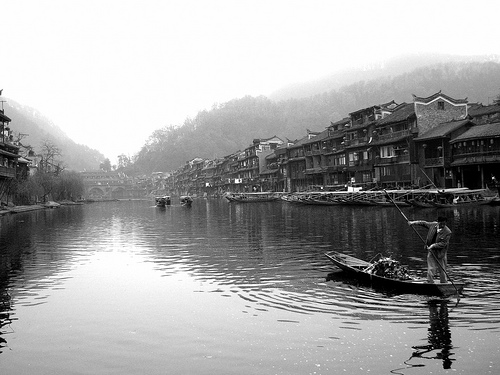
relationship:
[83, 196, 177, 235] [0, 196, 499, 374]
ripples in river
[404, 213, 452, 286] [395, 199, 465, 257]
he wears jacket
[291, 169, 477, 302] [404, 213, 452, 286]
boat with he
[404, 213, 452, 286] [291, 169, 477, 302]
he on boat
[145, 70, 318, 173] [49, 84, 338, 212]
forest on hill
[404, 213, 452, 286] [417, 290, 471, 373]
he has reflection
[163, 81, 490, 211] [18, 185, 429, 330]
buildings along river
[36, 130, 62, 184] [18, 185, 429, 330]
tree near river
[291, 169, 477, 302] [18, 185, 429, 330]
boat on river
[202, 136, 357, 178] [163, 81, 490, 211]
lights near buildings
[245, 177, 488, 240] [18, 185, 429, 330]
object near river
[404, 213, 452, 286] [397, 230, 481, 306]
he holds paddle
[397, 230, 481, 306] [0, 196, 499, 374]
paddle in river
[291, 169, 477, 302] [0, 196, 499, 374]
boat on river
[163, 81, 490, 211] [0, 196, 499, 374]
buildings on river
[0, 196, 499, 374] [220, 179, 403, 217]
river in front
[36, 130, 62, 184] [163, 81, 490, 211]
tree behind buildings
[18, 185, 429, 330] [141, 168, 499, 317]
river passing population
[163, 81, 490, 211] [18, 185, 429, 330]
houses on river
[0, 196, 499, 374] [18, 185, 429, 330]
river in river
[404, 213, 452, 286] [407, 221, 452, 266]
he wears suit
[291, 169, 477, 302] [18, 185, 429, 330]
boat in river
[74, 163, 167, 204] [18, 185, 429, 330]
bridge over river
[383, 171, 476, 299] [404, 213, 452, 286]
he holding he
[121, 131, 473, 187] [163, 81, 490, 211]
houses in row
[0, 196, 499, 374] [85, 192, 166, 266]
river has waves